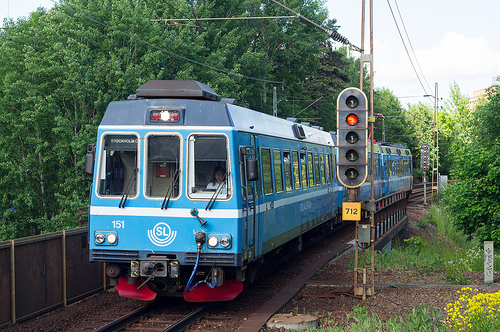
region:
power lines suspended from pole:
[371, 0, 441, 295]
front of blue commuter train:
[89, 79, 409, 300]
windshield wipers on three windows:
[95, 132, 229, 210]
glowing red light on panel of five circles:
[335, 87, 368, 188]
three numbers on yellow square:
[341, 202, 360, 219]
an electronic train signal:
[334, 85, 370, 187]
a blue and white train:
[87, 77, 336, 306]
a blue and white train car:
[330, 126, 381, 219]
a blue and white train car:
[375, 140, 412, 207]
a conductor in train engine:
[204, 167, 229, 192]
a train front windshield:
[187, 132, 228, 198]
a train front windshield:
[145, 132, 178, 199]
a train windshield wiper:
[159, 166, 182, 210]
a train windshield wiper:
[204, 159, 230, 210]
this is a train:
[57, 68, 417, 279]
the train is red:
[112, 247, 237, 308]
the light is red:
[317, 84, 448, 221]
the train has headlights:
[108, 95, 208, 153]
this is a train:
[57, 62, 430, 307]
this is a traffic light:
[336, 83, 367, 110]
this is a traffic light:
[348, 116, 360, 128]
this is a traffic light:
[337, 143, 368, 170]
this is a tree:
[26, 42, 73, 234]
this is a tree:
[456, 98, 496, 225]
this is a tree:
[5, 58, 103, 263]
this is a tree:
[52, 8, 129, 123]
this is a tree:
[216, 20, 319, 114]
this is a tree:
[299, 11, 373, 117]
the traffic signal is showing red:
[337, 87, 367, 190]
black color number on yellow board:
[340, 201, 362, 220]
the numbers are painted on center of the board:
[340, 199, 360, 220]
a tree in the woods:
[3, 19, 62, 234]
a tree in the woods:
[447, 85, 497, 265]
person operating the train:
[201, 161, 230, 198]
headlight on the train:
[206, 237, 230, 250]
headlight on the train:
[93, 230, 118, 250]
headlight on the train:
[155, 108, 175, 125]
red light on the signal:
[343, 110, 360, 127]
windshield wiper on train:
[201, 162, 229, 212]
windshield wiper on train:
[154, 153, 179, 213]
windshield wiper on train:
[113, 148, 145, 209]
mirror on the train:
[236, 139, 265, 186]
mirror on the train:
[78, 138, 105, 179]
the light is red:
[346, 112, 358, 124]